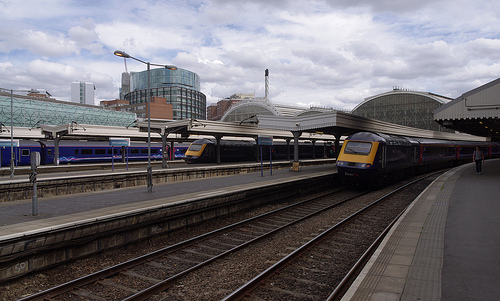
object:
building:
[432, 75, 499, 140]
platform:
[344, 156, 497, 297]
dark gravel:
[218, 219, 293, 286]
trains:
[174, 130, 496, 175]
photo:
[3, 6, 494, 298]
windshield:
[341, 139, 377, 155]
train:
[331, 127, 498, 189]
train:
[181, 135, 434, 166]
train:
[1, 139, 330, 166]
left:
[219, 139, 260, 161]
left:
[314, 140, 334, 156]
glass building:
[115, 70, 209, 122]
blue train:
[0, 140, 185, 164]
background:
[2, 3, 332, 237]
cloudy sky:
[3, 2, 498, 102]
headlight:
[333, 159, 368, 168]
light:
[337, 160, 342, 166]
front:
[335, 138, 376, 163]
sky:
[2, 2, 498, 107]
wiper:
[348, 147, 353, 153]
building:
[121, 66, 206, 118]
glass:
[130, 70, 197, 90]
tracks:
[277, 218, 369, 287]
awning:
[428, 76, 498, 138]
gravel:
[305, 216, 358, 253]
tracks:
[9, 149, 337, 298]